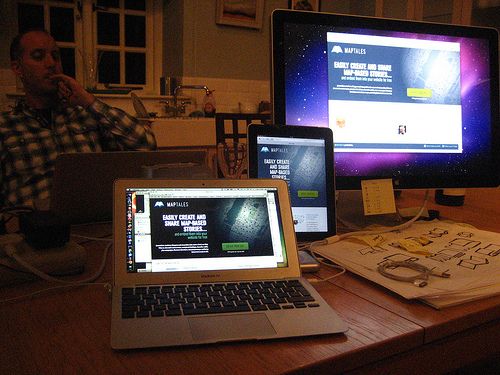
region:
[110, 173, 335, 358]
laptop computer on desk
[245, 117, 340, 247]
tablet computer on desk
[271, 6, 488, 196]
desktop computer on surface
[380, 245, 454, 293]
usb cord on table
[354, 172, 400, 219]
piece of paper taped to computer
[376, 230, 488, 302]
stack of papers on table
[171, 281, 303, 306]
black keyboard on laptop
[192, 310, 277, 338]
track pad on laptop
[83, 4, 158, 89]
window with glass panes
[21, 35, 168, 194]
person in plaid shirt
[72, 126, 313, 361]
a computer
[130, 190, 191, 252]
a computer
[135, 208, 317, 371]
a computer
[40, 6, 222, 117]
white window framed pane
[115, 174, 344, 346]
silver and black macbook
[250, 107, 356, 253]
black apple ipad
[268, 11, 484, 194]
black apple desktop computer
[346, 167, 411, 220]
sticky note on computer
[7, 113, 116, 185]
black and white checkered shirt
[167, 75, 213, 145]
silve large farm sink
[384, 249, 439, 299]
cable usb for apple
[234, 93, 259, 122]
white ceramic tea pot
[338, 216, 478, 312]
stack of white paper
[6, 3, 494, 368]
photo taken of dinner table in the kitchen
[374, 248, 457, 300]
a USB cord on top of the paper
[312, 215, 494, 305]
a folded paper on top of the table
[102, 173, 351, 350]
an opened computer laptop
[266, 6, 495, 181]
computer monitor with advertising on it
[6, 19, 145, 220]
a man wearing a checkered shirt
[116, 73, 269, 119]
a white stone backsplash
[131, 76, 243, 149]
a large kitchen sink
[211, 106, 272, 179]
the back rest of a dining chair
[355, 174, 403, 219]
one small post it note on the computer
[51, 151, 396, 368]
a laptop on table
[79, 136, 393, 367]
this is a macbook air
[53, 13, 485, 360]
four types of computers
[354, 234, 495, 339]
ipod cables on papers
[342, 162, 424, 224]
this is a yellow post it note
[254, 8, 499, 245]
a large apple monitor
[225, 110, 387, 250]
an ipad propped up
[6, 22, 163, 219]
this man wears plaid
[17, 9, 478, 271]
they are working in a kitchen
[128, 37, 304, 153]
the kitchen sink in background